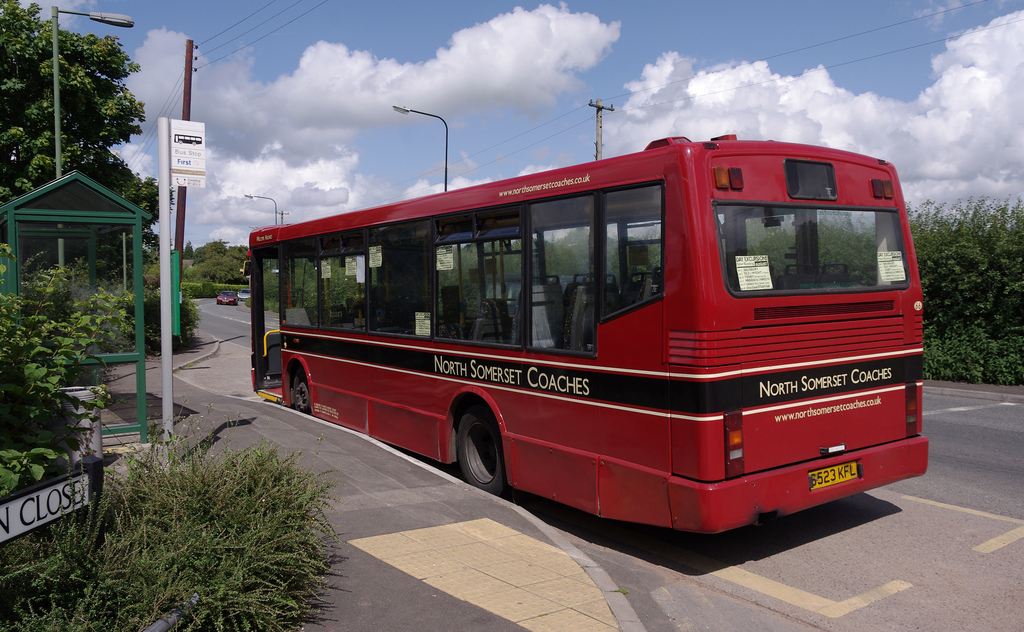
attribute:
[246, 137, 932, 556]
bus — red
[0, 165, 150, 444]
bus stop — green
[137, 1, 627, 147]
cloud — white, fluffy, large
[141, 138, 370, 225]
cloud — white, fluffy, large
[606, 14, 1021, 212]
cloud — white, fluffy, large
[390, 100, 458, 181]
street light — gray, tall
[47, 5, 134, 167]
street light — tall, gray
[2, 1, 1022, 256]
sky — blue